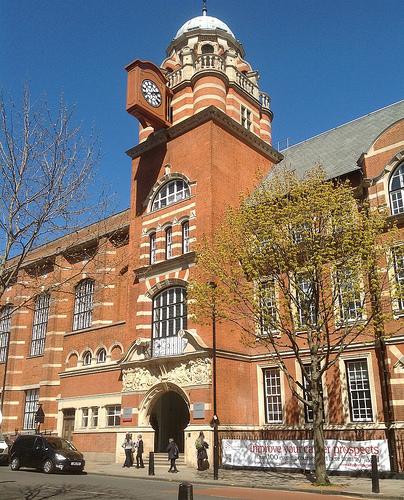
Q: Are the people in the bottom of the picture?
A: Yes, the people are in the bottom of the image.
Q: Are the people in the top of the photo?
A: No, the people are in the bottom of the image.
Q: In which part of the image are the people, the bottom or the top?
A: The people are in the bottom of the image.